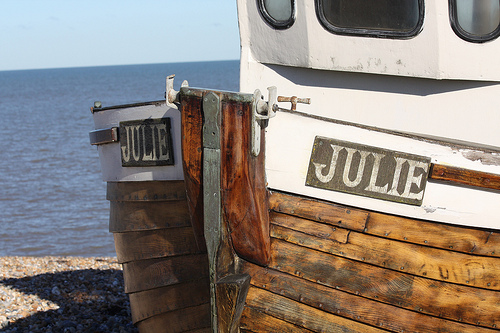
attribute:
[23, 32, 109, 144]
sea — calm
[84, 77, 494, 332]
wood — brown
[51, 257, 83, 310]
ground — filled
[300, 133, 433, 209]
name — title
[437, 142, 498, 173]
paint — peeling 